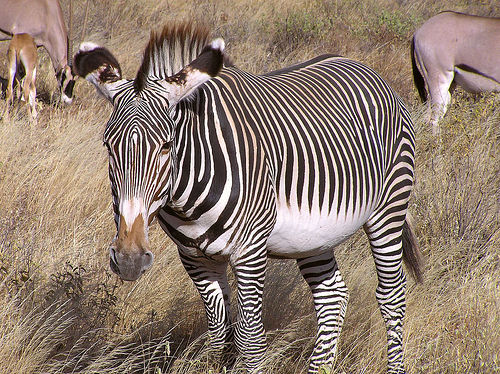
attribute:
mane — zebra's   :
[137, 20, 226, 85]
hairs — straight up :
[141, 40, 174, 64]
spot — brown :
[116, 207, 146, 249]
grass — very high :
[8, 146, 67, 328]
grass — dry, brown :
[10, 130, 460, 367]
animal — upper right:
[403, 0, 483, 145]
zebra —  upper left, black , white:
[60, 22, 433, 352]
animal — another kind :
[2, 8, 78, 123]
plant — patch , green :
[272, 10, 342, 50]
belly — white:
[254, 193, 368, 263]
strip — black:
[368, 226, 409, 243]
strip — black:
[373, 254, 405, 269]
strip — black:
[371, 221, 404, 240]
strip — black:
[369, 210, 409, 224]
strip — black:
[383, 180, 406, 204]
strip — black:
[298, 256, 335, 270]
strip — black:
[300, 265, 343, 284]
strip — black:
[317, 306, 343, 316]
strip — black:
[188, 270, 218, 282]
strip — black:
[233, 261, 267, 281]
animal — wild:
[7, 30, 47, 130]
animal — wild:
[409, 6, 497, 127]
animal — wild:
[83, 30, 428, 363]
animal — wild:
[6, 6, 76, 100]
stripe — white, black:
[319, 76, 365, 144]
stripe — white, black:
[305, 95, 337, 142]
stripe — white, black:
[295, 109, 325, 163]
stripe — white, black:
[284, 110, 322, 186]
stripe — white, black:
[294, 101, 335, 176]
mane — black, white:
[133, 24, 221, 81]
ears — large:
[74, 34, 228, 95]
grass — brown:
[3, 0, 499, 370]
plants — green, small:
[265, 2, 415, 58]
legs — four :
[183, 220, 413, 367]